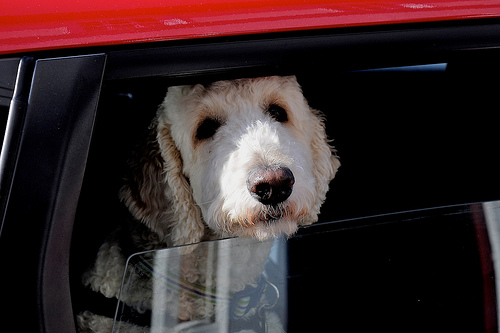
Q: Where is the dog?
A: In the red car.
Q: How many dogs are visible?
A: One.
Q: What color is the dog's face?
A: White.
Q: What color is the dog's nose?
A: Black.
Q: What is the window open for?
A: To give the dog fresh air.